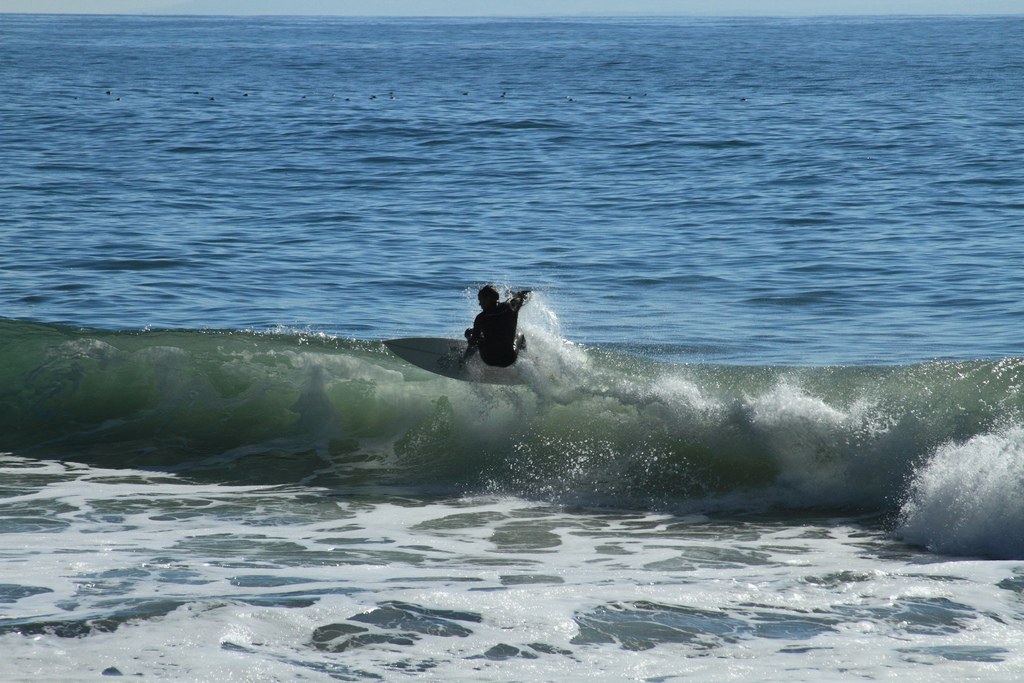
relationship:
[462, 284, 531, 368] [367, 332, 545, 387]
man on surfboard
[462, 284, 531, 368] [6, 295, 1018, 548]
man on wave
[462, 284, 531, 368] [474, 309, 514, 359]
man wearing black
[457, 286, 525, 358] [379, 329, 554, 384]
man standing on surfboard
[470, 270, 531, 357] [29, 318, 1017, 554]
man riding wave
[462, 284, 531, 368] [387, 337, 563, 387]
man riding surfboard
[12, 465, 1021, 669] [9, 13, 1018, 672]
part of water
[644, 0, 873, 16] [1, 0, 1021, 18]
patch of sky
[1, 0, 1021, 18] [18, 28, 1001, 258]
sky above water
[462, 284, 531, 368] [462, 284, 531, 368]
man wearing man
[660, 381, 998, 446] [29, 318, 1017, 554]
top of wave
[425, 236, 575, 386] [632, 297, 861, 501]
surfer riding water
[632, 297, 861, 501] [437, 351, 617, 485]
water in ocean